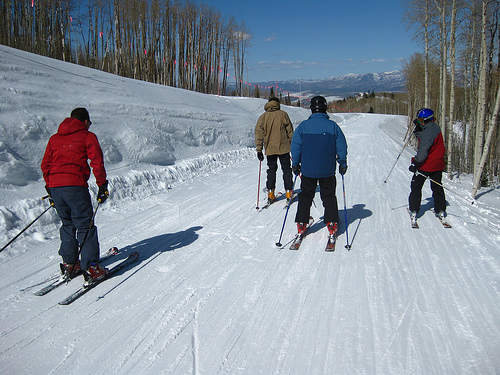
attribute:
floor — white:
[4, 110, 497, 372]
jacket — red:
[35, 116, 109, 192]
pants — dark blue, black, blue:
[44, 183, 100, 263]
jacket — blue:
[289, 110, 350, 185]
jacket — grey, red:
[409, 125, 451, 176]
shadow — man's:
[89, 217, 208, 287]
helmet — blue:
[418, 108, 434, 124]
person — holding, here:
[34, 106, 113, 282]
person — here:
[273, 93, 359, 251]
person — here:
[243, 94, 300, 212]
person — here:
[379, 104, 498, 228]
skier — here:
[6, 104, 139, 309]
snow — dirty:
[1, 44, 500, 371]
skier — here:
[272, 92, 360, 254]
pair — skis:
[287, 217, 343, 258]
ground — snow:
[3, 44, 500, 364]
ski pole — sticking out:
[65, 200, 104, 289]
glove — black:
[96, 178, 110, 207]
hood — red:
[55, 115, 86, 138]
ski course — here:
[3, 111, 499, 372]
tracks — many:
[5, 111, 498, 372]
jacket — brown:
[252, 99, 297, 162]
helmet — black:
[311, 95, 327, 112]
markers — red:
[0, 0, 303, 96]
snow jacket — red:
[41, 117, 111, 195]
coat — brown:
[254, 102, 301, 162]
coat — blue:
[289, 108, 352, 182]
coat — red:
[407, 121, 451, 174]